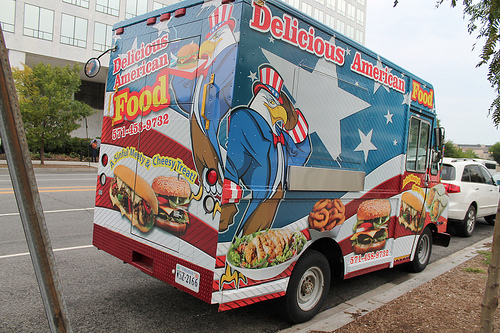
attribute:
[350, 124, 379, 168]
star — white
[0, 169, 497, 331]
roadway — concrete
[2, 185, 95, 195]
stripes — yellow, white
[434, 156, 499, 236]
suv — white, parked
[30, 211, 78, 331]
pole — rusty, metal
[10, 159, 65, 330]
pole — metal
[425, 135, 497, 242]
car — white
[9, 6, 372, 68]
building — white, stone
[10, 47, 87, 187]
tree — young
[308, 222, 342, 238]
container — paper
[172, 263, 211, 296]
plate — virginia , license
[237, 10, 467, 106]
sign — street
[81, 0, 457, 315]
truck — parked, food 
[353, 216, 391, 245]
cheeseburger — double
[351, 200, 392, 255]
bun — sesame seed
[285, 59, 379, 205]
window — closed